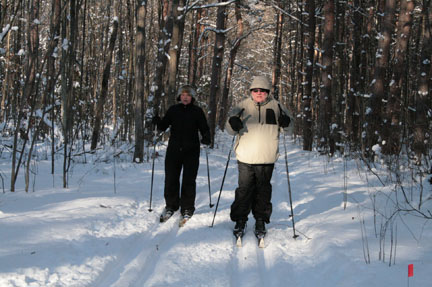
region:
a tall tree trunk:
[130, 23, 147, 158]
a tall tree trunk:
[208, 53, 220, 145]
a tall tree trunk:
[299, 64, 315, 142]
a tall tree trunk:
[313, 68, 333, 148]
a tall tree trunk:
[344, 69, 361, 151]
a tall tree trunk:
[363, 74, 380, 168]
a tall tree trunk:
[55, 81, 71, 138]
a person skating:
[129, 75, 214, 226]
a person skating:
[216, 72, 304, 246]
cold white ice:
[29, 198, 220, 285]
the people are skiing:
[105, 51, 343, 284]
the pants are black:
[132, 121, 296, 259]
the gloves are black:
[140, 109, 317, 154]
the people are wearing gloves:
[137, 106, 299, 141]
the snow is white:
[40, 186, 169, 264]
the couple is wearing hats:
[163, 69, 309, 128]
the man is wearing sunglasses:
[229, 78, 307, 110]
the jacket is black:
[122, 93, 241, 159]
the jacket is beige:
[217, 77, 301, 188]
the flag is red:
[407, 259, 420, 283]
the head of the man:
[247, 72, 273, 104]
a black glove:
[227, 112, 247, 132]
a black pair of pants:
[226, 157, 277, 226]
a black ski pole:
[204, 143, 216, 209]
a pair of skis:
[231, 215, 272, 253]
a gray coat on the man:
[223, 75, 292, 166]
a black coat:
[152, 101, 218, 152]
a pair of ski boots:
[232, 216, 267, 238]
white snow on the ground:
[0, 122, 430, 286]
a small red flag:
[405, 261, 415, 277]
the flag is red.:
[393, 255, 417, 283]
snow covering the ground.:
[8, 56, 415, 284]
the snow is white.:
[19, 178, 339, 285]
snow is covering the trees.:
[12, 9, 427, 152]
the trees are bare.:
[15, 13, 428, 133]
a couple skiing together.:
[120, 55, 339, 258]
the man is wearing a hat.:
[227, 61, 282, 102]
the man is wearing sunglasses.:
[232, 78, 273, 100]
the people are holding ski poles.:
[112, 46, 327, 262]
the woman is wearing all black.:
[154, 74, 215, 224]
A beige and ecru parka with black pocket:
[216, 68, 302, 162]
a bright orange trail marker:
[382, 238, 425, 281]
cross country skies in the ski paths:
[116, 201, 317, 281]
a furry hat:
[168, 77, 202, 114]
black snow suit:
[151, 104, 208, 214]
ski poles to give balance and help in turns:
[134, 113, 162, 215]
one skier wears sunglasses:
[250, 79, 268, 94]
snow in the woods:
[7, 4, 146, 240]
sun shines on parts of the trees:
[162, 11, 318, 80]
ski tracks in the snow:
[65, 239, 335, 281]